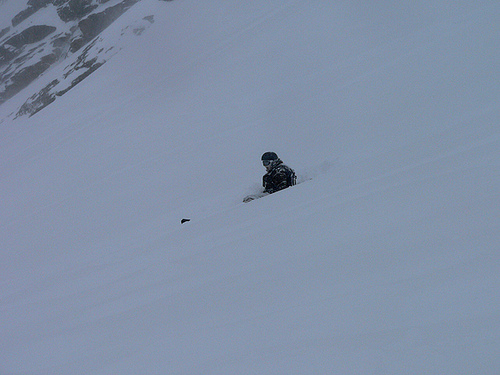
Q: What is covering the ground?
A: White snow.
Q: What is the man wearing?
A: A snowsuit.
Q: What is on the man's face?
A: Goggles.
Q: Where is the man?
A: On a snowy mountain.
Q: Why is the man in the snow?
A: The man fell.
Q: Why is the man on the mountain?
A: He's skiing.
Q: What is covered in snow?
A: The mountain.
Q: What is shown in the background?
A: Rocks.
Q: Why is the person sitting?
A: They fell.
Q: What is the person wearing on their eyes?
A: Goggles.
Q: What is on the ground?
A: Snow.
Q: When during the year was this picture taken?
A: Winter.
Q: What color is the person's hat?
A: Black.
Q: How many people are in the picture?
A: 1.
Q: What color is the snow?
A: White.